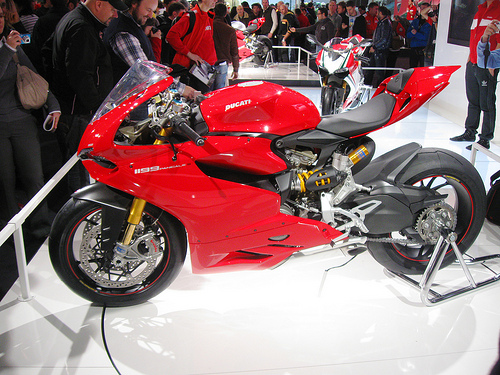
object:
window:
[85, 59, 181, 128]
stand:
[383, 226, 498, 307]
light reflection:
[0, 146, 94, 336]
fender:
[69, 181, 129, 217]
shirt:
[114, 31, 188, 97]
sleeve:
[104, 99, 122, 111]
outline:
[64, 206, 106, 281]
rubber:
[47, 192, 189, 308]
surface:
[311, 90, 396, 139]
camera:
[14, 32, 35, 46]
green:
[44, 151, 57, 160]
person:
[208, 3, 241, 91]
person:
[406, 0, 433, 68]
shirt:
[402, 12, 432, 49]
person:
[260, 0, 281, 63]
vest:
[254, 5, 283, 35]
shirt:
[48, 3, 129, 117]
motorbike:
[45, 58, 488, 308]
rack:
[380, 222, 500, 307]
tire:
[365, 145, 490, 275]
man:
[474, 21, 498, 72]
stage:
[0, 44, 499, 374]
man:
[447, 0, 500, 151]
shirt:
[466, 1, 500, 68]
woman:
[0, 6, 74, 243]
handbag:
[13, 51, 50, 111]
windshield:
[90, 59, 175, 127]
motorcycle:
[305, 32, 378, 118]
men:
[108, 0, 201, 101]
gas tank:
[197, 81, 322, 136]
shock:
[121, 196, 151, 247]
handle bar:
[167, 113, 210, 147]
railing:
[1, 152, 81, 308]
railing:
[262, 45, 320, 79]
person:
[255, 1, 283, 61]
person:
[335, 1, 370, 43]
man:
[166, 1, 219, 94]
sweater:
[165, 4, 220, 72]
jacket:
[407, 17, 434, 49]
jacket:
[210, 15, 243, 66]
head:
[87, 0, 125, 28]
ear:
[92, 1, 104, 10]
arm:
[62, 20, 106, 109]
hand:
[194, 54, 212, 67]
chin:
[142, 23, 149, 27]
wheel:
[44, 181, 188, 308]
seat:
[315, 91, 397, 138]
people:
[293, 7, 311, 58]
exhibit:
[2, 1, 500, 374]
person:
[370, 7, 398, 86]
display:
[47, 54, 489, 319]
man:
[45, 1, 133, 195]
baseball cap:
[100, 0, 136, 17]